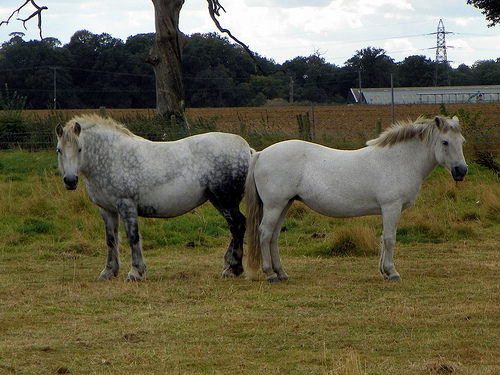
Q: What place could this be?
A: It is a field.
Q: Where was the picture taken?
A: It was taken at the field.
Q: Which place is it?
A: It is a field.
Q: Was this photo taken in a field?
A: Yes, it was taken in a field.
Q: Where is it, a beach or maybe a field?
A: It is a field.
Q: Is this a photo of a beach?
A: No, the picture is showing a field.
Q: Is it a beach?
A: No, it is a field.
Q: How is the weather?
A: It is cloudy.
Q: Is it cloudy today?
A: Yes, it is cloudy.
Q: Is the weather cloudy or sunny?
A: It is cloudy.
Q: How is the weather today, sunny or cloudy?
A: It is cloudy.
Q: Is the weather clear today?
A: No, it is cloudy.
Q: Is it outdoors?
A: Yes, it is outdoors.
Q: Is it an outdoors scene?
A: Yes, it is outdoors.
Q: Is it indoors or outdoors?
A: It is outdoors.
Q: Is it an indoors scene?
A: No, it is outdoors.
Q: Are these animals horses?
A: Yes, all the animals are horses.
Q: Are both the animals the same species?
A: Yes, all the animals are horses.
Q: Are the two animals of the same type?
A: Yes, all the animals are horses.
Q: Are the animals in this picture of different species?
A: No, all the animals are horses.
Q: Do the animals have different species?
A: No, all the animals are horses.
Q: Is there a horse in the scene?
A: Yes, there is a horse.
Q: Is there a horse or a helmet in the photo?
A: Yes, there is a horse.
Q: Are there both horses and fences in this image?
A: Yes, there are both a horse and a fence.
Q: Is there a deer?
A: No, there is no deer.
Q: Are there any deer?
A: No, there are no deer.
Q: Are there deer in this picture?
A: No, there are no deer.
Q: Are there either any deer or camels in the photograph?
A: No, there are no deer or camels.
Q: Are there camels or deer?
A: No, there are no deer or camels.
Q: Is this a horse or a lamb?
A: This is a horse.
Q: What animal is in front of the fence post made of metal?
A: The horse is in front of the fence post.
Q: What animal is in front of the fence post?
A: The horse is in front of the fence post.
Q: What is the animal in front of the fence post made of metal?
A: The animal is a horse.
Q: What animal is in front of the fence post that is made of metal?
A: The animal is a horse.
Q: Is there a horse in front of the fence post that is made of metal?
A: Yes, there is a horse in front of the fence post.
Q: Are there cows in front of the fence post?
A: No, there is a horse in front of the fence post.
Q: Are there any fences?
A: Yes, there is a fence.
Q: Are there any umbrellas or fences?
A: Yes, there is a fence.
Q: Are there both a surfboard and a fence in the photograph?
A: No, there is a fence but no surfboards.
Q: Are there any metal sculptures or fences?
A: Yes, there is a metal fence.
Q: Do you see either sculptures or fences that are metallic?
A: Yes, the fence is metallic.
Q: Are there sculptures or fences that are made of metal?
A: Yes, the fence is made of metal.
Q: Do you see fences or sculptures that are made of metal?
A: Yes, the fence is made of metal.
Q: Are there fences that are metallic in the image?
A: Yes, there is a metal fence.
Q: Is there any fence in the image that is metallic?
A: Yes, there is a fence that is metallic.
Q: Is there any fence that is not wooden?
A: Yes, there is a metallic fence.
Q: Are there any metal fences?
A: Yes, there is a fence that is made of metal.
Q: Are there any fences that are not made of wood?
A: Yes, there is a fence that is made of metal.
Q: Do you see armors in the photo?
A: No, there are no armors.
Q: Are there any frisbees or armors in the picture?
A: No, there are no armors or frisbees.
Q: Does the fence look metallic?
A: Yes, the fence is metallic.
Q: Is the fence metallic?
A: Yes, the fence is metallic.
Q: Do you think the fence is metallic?
A: Yes, the fence is metallic.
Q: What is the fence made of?
A: The fence is made of metal.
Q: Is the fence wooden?
A: No, the fence is metallic.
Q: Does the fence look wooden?
A: No, the fence is metallic.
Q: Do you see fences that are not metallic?
A: No, there is a fence but it is metallic.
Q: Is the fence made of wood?
A: No, the fence is made of metal.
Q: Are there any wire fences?
A: No, there is a fence but it is made of metal.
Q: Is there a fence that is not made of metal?
A: No, there is a fence but it is made of metal.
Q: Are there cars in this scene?
A: No, there are no cars.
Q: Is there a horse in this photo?
A: Yes, there is a horse.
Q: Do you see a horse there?
A: Yes, there is a horse.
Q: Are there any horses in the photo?
A: Yes, there is a horse.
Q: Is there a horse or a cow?
A: Yes, there is a horse.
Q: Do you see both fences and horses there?
A: Yes, there are both a horse and a fence.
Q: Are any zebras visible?
A: No, there are no zebras.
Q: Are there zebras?
A: No, there are no zebras.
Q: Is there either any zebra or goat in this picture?
A: No, there are no zebras or goats.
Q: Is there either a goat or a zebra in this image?
A: No, there are no zebras or goats.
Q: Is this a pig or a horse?
A: This is a horse.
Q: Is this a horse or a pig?
A: This is a horse.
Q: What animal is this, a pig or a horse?
A: This is a horse.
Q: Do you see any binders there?
A: No, there are no binders.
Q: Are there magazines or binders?
A: No, there are no binders or magazines.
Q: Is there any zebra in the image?
A: No, there are no zebras.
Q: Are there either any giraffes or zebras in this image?
A: No, there are no zebras or giraffes.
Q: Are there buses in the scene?
A: No, there are no buses.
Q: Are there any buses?
A: No, there are no buses.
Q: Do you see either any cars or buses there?
A: No, there are no buses or cars.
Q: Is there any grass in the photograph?
A: Yes, there is grass.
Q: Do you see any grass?
A: Yes, there is grass.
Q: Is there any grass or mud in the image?
A: Yes, there is grass.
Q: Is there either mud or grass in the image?
A: Yes, there is grass.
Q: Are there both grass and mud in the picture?
A: No, there is grass but no mud.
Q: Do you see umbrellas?
A: No, there are no umbrellas.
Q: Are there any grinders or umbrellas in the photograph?
A: No, there are no umbrellas or grinders.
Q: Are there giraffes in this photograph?
A: No, there are no giraffes.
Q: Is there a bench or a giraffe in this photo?
A: No, there are no giraffes or benches.